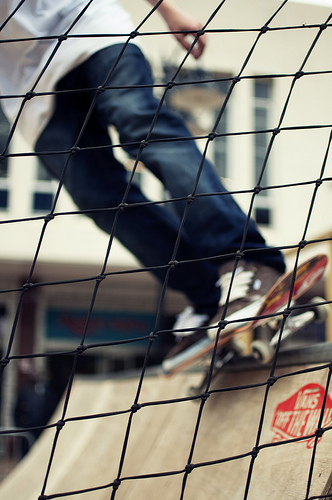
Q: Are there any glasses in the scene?
A: No, there are no glasses.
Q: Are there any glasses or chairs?
A: No, there are no glasses or chairs.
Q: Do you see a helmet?
A: No, there are no helmets.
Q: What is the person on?
A: The person is on the skateboard.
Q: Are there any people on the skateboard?
A: Yes, there is a person on the skateboard.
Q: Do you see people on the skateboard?
A: Yes, there is a person on the skateboard.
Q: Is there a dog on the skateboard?
A: No, there is a person on the skateboard.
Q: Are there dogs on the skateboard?
A: No, there is a person on the skateboard.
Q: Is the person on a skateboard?
A: Yes, the person is on a skateboard.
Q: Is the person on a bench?
A: No, the person is on a skateboard.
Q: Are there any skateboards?
A: Yes, there is a skateboard.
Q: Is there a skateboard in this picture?
A: Yes, there is a skateboard.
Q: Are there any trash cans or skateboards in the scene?
A: Yes, there is a skateboard.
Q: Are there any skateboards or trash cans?
A: Yes, there is a skateboard.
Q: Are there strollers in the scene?
A: No, there are no strollers.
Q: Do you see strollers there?
A: No, there are no strollers.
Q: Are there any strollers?
A: No, there are no strollers.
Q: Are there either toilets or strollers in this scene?
A: No, there are no strollers or toilets.